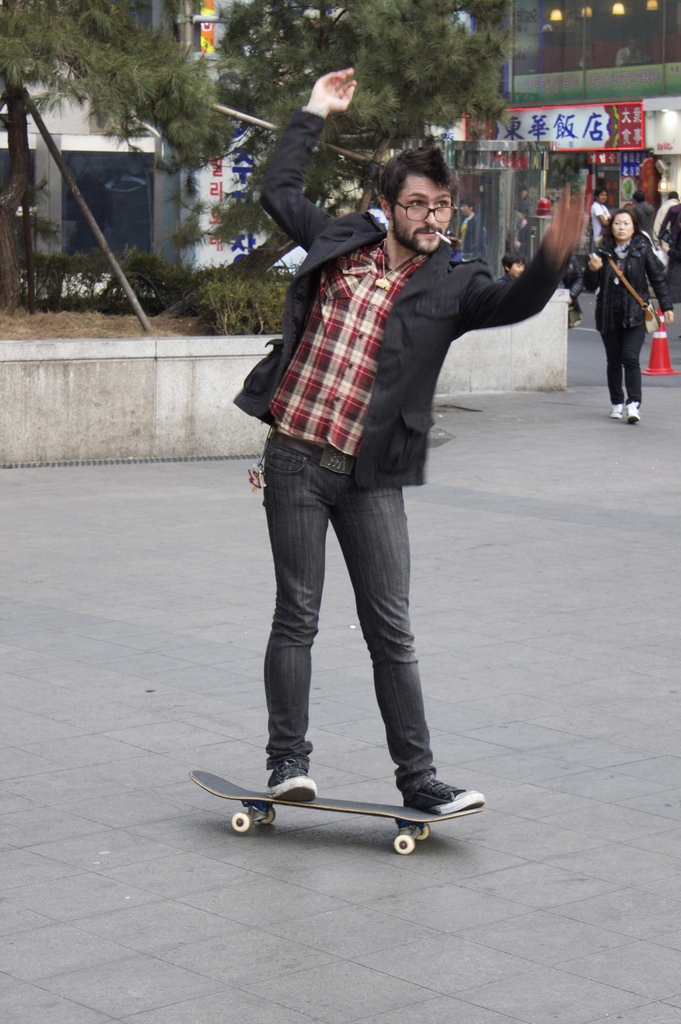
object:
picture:
[0, 5, 680, 1016]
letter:
[465, 101, 644, 151]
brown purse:
[605, 255, 662, 334]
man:
[229, 65, 594, 816]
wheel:
[230, 811, 251, 833]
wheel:
[260, 807, 276, 826]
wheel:
[393, 832, 415, 856]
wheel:
[414, 821, 431, 841]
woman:
[587, 206, 674, 422]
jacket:
[583, 232, 673, 336]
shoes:
[609, 402, 641, 426]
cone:
[640, 306, 676, 377]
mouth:
[415, 230, 443, 236]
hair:
[380, 132, 466, 204]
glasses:
[394, 198, 458, 223]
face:
[393, 170, 451, 255]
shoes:
[266, 756, 486, 817]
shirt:
[268, 225, 431, 458]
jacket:
[230, 107, 571, 496]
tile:
[482, 895, 580, 963]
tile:
[352, 925, 540, 994]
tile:
[495, 933, 632, 1023]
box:
[0, 288, 573, 466]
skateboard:
[188, 766, 484, 857]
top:
[188, 766, 484, 824]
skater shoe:
[403, 770, 486, 816]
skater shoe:
[265, 769, 318, 805]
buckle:
[318, 444, 352, 476]